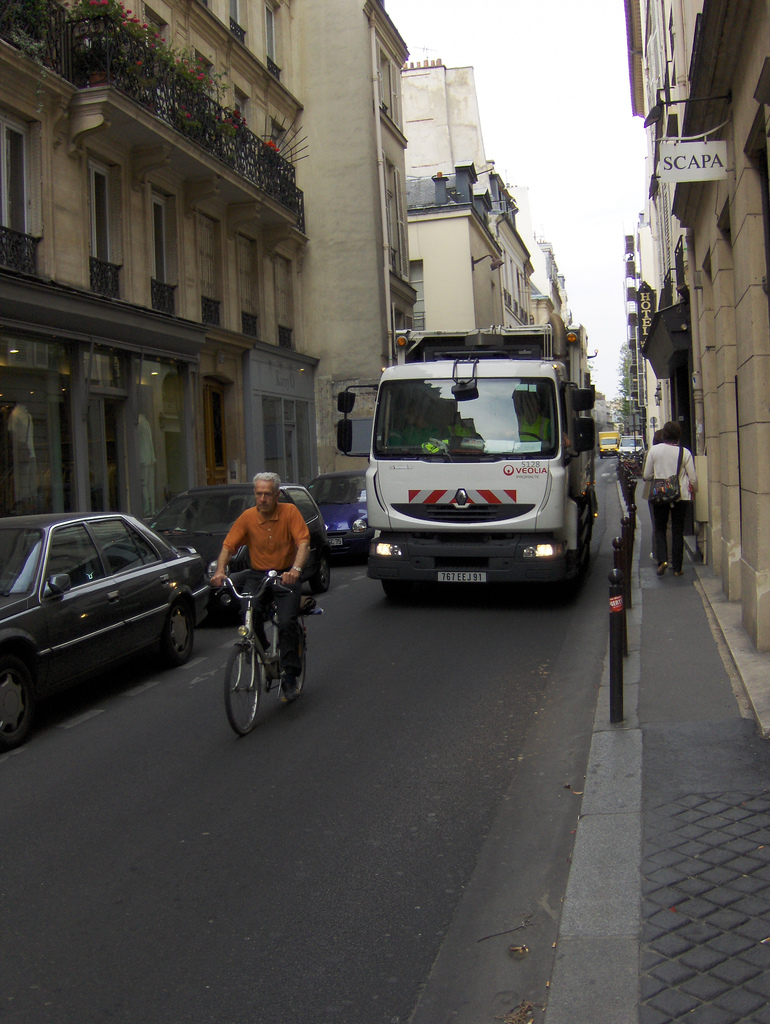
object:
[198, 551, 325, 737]
bike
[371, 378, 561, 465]
window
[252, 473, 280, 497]
hair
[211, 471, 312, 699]
man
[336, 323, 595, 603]
truck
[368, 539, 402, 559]
headlight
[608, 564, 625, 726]
pole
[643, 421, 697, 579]
woman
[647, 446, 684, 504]
bag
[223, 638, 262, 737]
wheel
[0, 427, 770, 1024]
road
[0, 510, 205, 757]
car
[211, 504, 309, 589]
shirt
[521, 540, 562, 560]
headlight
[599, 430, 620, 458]
truck